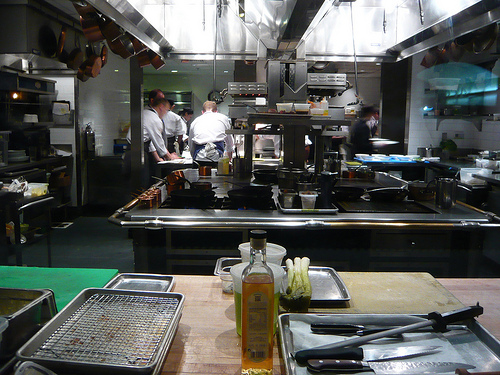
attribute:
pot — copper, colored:
[148, 50, 164, 72]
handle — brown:
[290, 343, 369, 367]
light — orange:
[10, 92, 19, 101]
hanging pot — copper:
[149, 50, 169, 69]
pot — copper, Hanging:
[115, 34, 142, 56]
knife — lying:
[301, 356, 480, 373]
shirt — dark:
[187, 120, 275, 161]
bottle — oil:
[241, 225, 274, 372]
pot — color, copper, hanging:
[102, 24, 124, 42]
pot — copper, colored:
[42, 20, 109, 82]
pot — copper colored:
[45, 18, 104, 82]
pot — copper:
[69, 3, 109, 51]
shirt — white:
[124, 106, 170, 157]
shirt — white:
[185, 107, 236, 157]